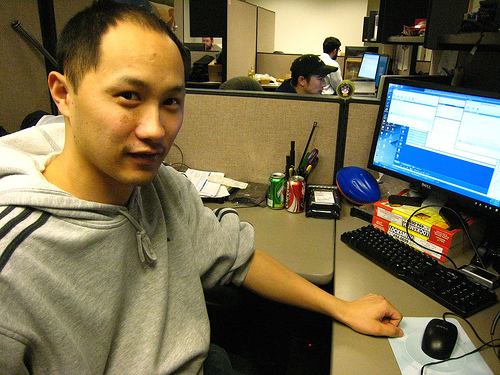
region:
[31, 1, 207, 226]
Man looking at the camera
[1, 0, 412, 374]
Man wearing a gray hoodie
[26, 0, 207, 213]
He is an asian man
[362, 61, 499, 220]
Computer monitor is on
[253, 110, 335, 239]
Two soda cans on the table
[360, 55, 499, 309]
Computer monitor standing on books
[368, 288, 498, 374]
Mouse sitting on mouse pad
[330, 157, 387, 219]
Blue football on the desk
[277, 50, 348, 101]
Man wearing a hat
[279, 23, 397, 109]
Men working on their computers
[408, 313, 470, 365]
black computer mouse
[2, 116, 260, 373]
grey sweatshirt with hood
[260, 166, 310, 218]
red and green soda cans on desk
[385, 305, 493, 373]
grey mouse pad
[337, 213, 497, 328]
black computer keyboard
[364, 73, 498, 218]
computer monitor on stack of phonebooks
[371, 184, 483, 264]
stack of yellow phone books on desk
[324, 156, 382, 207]
blue and red foam football on desk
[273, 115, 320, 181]
cup of pencils on desk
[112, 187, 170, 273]
drawstring on front of grey sweatshirt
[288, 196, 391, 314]
this is an office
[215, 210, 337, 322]
this is a cubicle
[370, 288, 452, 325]
this is a mouse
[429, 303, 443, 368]
the mouse is black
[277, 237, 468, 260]
this is a keyboard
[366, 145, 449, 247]
this is a screen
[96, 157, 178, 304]
this is a man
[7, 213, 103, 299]
this is a sweatshirt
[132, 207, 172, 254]
this is a tie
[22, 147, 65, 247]
this is a hoodie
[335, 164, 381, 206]
A blue and orange football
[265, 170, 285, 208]
A green aluminum can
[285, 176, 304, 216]
A red aluminum can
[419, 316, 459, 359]
A black computer mouse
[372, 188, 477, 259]
A stack of books on the desk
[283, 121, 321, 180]
Pens in a pen holder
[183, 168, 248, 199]
Papers piled on the desk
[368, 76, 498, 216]
A bright computer monitor on the books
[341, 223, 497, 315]
A slim black computer keyboard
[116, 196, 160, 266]
Strings on a gray hoodie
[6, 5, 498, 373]
man sitting in a cubicle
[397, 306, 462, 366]
mouse to a computer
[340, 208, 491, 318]
keyboard to a computer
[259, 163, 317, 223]
cans of soda on desk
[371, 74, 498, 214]
computer screen on a desk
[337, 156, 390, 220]
blue football on desk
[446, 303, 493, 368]
black wire to a mouse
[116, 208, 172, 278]
string to man's hoodie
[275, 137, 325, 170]
pens and scissor in a cup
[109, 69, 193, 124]
eyes of an Asian man